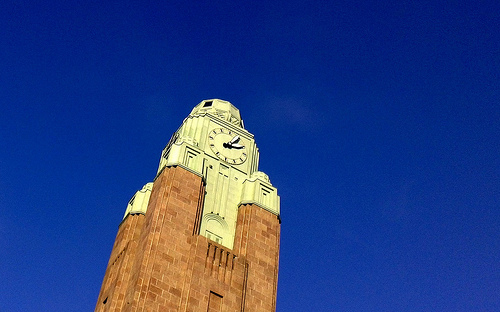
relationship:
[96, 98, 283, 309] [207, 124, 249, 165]
tower has a clock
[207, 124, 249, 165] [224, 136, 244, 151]
clock has hands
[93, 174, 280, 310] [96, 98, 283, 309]
columns are around tower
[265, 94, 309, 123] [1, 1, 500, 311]
clouds are in sky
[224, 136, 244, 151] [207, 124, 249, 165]
hands are on a clock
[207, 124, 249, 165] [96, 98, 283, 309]
clock on a tower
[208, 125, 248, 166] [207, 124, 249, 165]
numerals are on a clock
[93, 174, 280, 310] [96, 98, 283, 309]
columns are on a tower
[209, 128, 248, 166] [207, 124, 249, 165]
time on a clock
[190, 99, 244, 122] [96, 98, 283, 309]
cap on a tower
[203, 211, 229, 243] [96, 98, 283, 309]
arch on a tower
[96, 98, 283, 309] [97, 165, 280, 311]
tower has brick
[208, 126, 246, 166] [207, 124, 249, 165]
numbers are on a clock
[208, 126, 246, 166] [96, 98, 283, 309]
numbers are on a tower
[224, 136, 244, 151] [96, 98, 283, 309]
hands are on a tower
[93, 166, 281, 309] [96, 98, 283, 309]
bricks are on a tower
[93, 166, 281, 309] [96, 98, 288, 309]
bricks are on front of tower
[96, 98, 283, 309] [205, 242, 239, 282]
tower has ridges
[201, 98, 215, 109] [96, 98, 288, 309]
square at top of tower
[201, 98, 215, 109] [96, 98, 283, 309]
square on front of tower